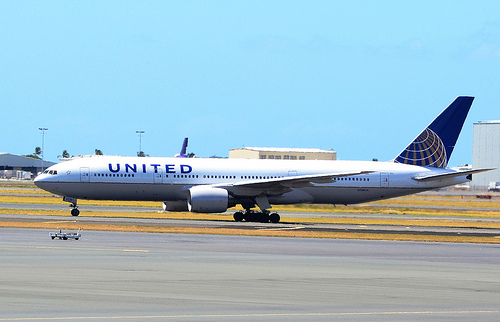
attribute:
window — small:
[44, 165, 61, 185]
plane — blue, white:
[8, 93, 480, 238]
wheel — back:
[63, 186, 107, 259]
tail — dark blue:
[394, 91, 471, 170]